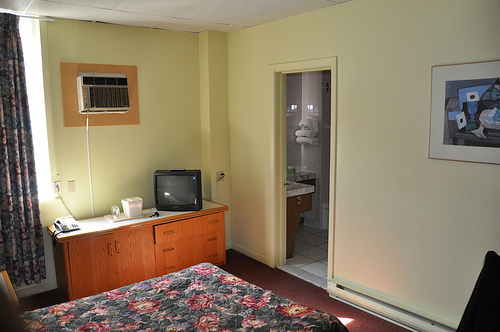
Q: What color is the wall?
A: Yellow.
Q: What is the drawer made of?
A: Wood.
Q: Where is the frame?
A: On the wall.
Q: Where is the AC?
A: On the wall.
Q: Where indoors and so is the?
A: Picture.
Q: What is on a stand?
A: A T.V.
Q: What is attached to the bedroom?
A: A bathroom.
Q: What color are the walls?
A: Light yellow.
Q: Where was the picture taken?
A: In a bedroom.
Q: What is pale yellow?
A: Walls.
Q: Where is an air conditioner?
A: On the wall.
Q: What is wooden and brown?
A: A dresser.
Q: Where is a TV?
A: On a dresser.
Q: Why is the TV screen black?
A: It's off.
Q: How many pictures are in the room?
A: 1.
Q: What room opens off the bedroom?
A: Bathroom.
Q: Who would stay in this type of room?
A: A traveler.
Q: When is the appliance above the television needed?
A: When it's hot.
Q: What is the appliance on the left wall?
A: Air conditioner.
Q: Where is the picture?
A: The right wall.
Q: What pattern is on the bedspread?
A: Floral.